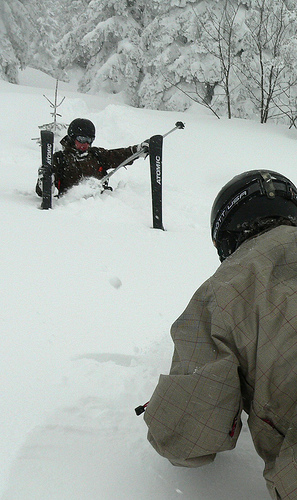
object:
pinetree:
[30, 74, 70, 146]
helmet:
[67, 118, 96, 144]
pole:
[100, 121, 185, 187]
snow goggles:
[76, 135, 95, 144]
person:
[143, 168, 297, 500]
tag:
[135, 401, 150, 416]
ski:
[40, 129, 54, 209]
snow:
[0, 0, 297, 500]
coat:
[143, 224, 297, 499]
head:
[212, 169, 297, 262]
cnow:
[31, 200, 70, 244]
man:
[35, 118, 151, 200]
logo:
[156, 155, 161, 186]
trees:
[191, 0, 259, 118]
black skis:
[149, 134, 167, 231]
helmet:
[209, 168, 297, 241]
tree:
[246, 0, 296, 132]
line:
[227, 274, 242, 295]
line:
[237, 307, 253, 324]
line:
[195, 299, 209, 322]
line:
[190, 393, 214, 405]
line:
[163, 399, 183, 413]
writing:
[46, 141, 52, 165]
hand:
[139, 138, 151, 158]